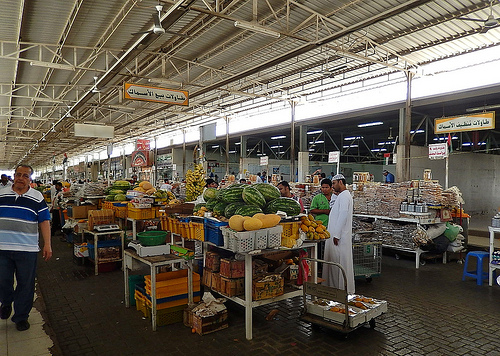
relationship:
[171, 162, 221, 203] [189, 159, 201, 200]
bananas hanging on rack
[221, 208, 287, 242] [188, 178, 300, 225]
mangoes beside watermelons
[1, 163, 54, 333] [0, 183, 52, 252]
man wearing shirt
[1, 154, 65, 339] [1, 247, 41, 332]
man wearing dark pants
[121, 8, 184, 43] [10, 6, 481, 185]
fan on ceiling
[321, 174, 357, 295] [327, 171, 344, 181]
he with cap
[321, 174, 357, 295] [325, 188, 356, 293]
he wearing robe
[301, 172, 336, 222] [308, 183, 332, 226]
woman in green shirt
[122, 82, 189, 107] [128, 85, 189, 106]
sign with writing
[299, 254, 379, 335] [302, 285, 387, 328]
cart with packages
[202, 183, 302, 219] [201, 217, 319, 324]
watermelons on table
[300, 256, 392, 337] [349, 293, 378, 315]
dolley carrying items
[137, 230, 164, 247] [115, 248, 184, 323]
bowl on table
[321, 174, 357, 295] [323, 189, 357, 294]
he wearing gown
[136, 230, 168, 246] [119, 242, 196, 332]
bowl on table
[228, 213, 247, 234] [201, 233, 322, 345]
canteloupe on table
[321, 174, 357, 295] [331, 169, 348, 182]
he wearing cap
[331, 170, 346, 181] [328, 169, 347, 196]
cap on man's head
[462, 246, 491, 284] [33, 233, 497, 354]
stool on floor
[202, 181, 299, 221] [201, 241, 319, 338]
watermelons on table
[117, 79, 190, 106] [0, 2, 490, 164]
sign hanging from ceiling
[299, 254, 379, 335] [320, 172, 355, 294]
cart next to man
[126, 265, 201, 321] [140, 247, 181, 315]
containers stacked under table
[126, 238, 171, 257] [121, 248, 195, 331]
scale on table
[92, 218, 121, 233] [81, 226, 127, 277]
scale on table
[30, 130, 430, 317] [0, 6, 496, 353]
people in market